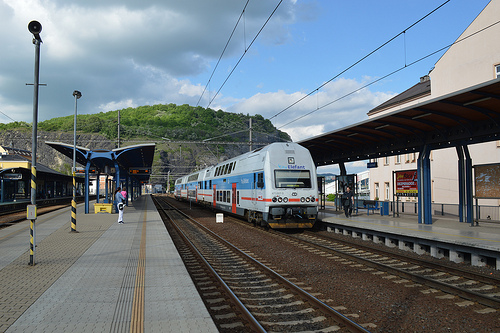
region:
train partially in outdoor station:
[169, 110, 489, 321]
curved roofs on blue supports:
[45, 130, 155, 210]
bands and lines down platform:
[5, 181, 210, 326]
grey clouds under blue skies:
[0, 0, 490, 140]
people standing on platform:
[110, 170, 130, 221]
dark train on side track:
[0, 160, 90, 210]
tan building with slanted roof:
[362, 5, 494, 217]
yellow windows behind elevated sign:
[367, 157, 419, 219]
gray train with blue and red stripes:
[175, 141, 320, 226]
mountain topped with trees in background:
[8, 101, 314, 226]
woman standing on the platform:
[113, 184, 126, 224]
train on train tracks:
[172, 138, 322, 232]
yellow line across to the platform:
[127, 193, 152, 332]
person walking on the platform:
[340, 184, 355, 221]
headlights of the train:
[271, 194, 319, 206]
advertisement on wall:
[389, 167, 420, 198]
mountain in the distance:
[0, 102, 296, 193]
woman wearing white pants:
[114, 186, 129, 226]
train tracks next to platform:
[148, 194, 372, 332]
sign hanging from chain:
[365, 156, 380, 168]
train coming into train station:
[168, 141, 311, 214]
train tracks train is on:
[290, 216, 498, 315]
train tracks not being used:
[162, 192, 333, 323]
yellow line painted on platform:
[126, 191, 146, 331]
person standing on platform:
[113, 189, 125, 218]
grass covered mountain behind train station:
[53, 100, 275, 135]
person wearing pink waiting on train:
[110, 184, 126, 223]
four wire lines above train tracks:
[201, 14, 492, 129]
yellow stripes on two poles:
[27, 162, 82, 263]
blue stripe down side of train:
[170, 175, 258, 192]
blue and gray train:
[199, 161, 303, 221]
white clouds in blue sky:
[51, 11, 91, 46]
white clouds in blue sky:
[58, 34, 109, 72]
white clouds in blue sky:
[103, 21, 173, 58]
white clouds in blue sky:
[98, 49, 158, 91]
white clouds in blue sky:
[159, 9, 201, 43]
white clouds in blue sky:
[159, 49, 214, 96]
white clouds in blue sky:
[283, 12, 354, 53]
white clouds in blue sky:
[266, 34, 354, 86]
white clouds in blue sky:
[225, 72, 306, 102]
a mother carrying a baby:
[108, 173, 143, 223]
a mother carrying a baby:
[98, 182, 132, 221]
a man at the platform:
[336, 173, 372, 220]